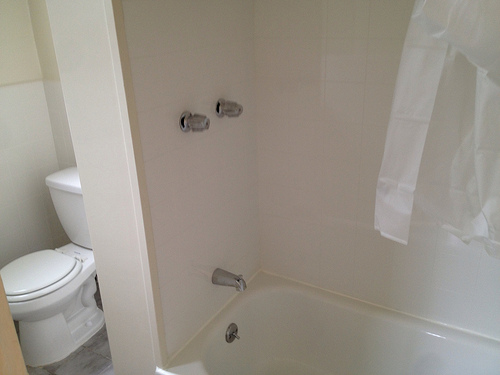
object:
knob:
[211, 95, 242, 119]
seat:
[0, 247, 82, 305]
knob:
[179, 114, 214, 131]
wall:
[114, 0, 255, 364]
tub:
[155, 272, 497, 372]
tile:
[0, 75, 73, 264]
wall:
[245, 0, 498, 340]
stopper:
[222, 320, 243, 342]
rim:
[259, 266, 499, 344]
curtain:
[375, 0, 498, 257]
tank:
[44, 164, 92, 252]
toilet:
[0, 165, 103, 367]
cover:
[0, 247, 75, 296]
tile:
[48, 349, 112, 374]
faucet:
[212, 268, 247, 292]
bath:
[162, 269, 498, 373]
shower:
[112, 2, 498, 372]